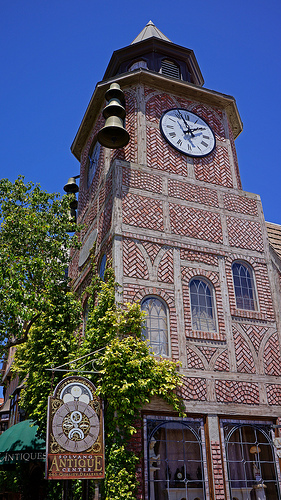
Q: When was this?
A: Daytime.